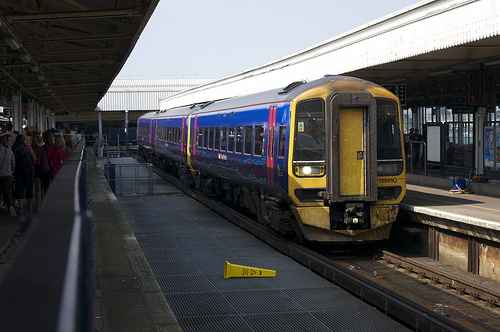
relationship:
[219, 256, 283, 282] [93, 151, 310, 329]
cone on ground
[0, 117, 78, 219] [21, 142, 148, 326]
people waiting on platform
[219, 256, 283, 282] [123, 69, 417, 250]
cone front of train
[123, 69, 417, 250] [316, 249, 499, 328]
train traveling on tracks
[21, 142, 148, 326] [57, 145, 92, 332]
platform has white sign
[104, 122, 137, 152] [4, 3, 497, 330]
gate in back photo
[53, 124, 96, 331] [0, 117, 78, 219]
railing front of passengers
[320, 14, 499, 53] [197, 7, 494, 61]
awning over top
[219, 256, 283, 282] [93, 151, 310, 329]
pylon laying on side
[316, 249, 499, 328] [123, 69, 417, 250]
tracks used by train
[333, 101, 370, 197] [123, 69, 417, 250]
door on front of train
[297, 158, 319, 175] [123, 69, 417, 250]
headlight on front of train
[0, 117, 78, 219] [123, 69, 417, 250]
travelers waiting board train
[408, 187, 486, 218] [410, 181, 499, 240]
shadow cast on ground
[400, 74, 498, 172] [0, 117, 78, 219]
windows on side passenger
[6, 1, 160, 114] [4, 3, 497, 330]
roof shelter from weather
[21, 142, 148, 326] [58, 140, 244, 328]
loading area at train station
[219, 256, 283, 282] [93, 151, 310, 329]
cone laying on ground